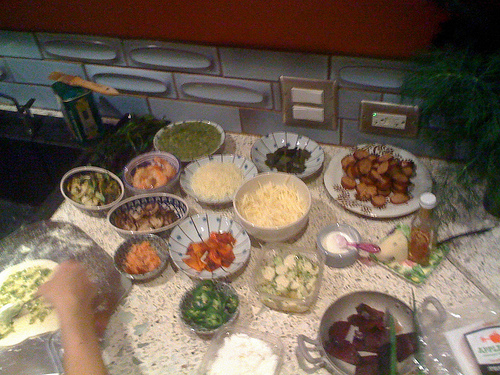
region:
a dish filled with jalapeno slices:
[181, 281, 238, 333]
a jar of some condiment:
[405, 189, 435, 272]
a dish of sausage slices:
[329, 138, 421, 204]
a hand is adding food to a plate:
[0, 256, 112, 373]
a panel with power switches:
[280, 72, 350, 138]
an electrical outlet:
[357, 101, 427, 133]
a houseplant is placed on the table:
[417, 23, 498, 236]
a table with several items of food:
[78, 111, 498, 373]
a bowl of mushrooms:
[108, 199, 185, 237]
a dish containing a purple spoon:
[311, 224, 383, 271]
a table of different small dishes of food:
[17, 61, 467, 356]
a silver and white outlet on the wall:
[359, 89, 430, 139]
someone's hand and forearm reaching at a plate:
[31, 266, 119, 374]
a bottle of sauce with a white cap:
[409, 186, 442, 278]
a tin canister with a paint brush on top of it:
[43, 64, 123, 148]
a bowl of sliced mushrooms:
[111, 193, 183, 239]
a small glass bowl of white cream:
[313, 225, 387, 267]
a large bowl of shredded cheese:
[238, 169, 309, 239]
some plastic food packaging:
[433, 298, 498, 372]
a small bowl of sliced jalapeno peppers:
[181, 278, 237, 335]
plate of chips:
[337, 140, 432, 220]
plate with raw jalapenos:
[181, 275, 244, 330]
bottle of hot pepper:
[402, 190, 455, 270]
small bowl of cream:
[310, 218, 366, 265]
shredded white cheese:
[232, 168, 321, 244]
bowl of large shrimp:
[124, 150, 186, 192]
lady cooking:
[6, 222, 111, 372]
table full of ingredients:
[60, 114, 461, 374]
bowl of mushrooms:
[105, 189, 199, 229]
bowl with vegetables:
[60, 161, 122, 215]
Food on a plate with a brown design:
[322, 137, 437, 217]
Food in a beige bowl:
[231, 167, 312, 240]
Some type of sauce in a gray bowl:
[313, 220, 368, 270]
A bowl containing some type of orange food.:
[163, 207, 252, 282]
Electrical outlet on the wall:
[355, 97, 422, 140]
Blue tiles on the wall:
[118, 42, 275, 115]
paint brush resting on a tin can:
[44, 62, 121, 147]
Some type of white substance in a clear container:
[197, 318, 287, 373]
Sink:
[1, 100, 116, 248]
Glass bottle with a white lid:
[404, 188, 443, 265]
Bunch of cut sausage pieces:
[325, 135, 433, 228]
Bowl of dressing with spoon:
[316, 218, 375, 268]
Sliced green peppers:
[172, 274, 255, 335]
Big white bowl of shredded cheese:
[216, 170, 324, 241]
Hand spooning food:
[5, 252, 125, 365]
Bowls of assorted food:
[84, 142, 443, 340]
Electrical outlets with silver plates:
[269, 64, 444, 164]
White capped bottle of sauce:
[397, 179, 452, 276]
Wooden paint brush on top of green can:
[31, 66, 147, 141]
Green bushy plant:
[368, 29, 492, 227]